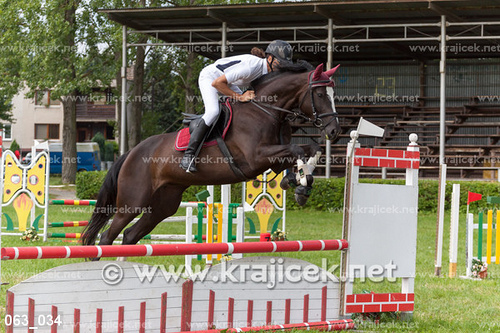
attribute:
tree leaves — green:
[5, 7, 91, 96]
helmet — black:
[266, 40, 295, 72]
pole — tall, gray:
[436, 11, 448, 171]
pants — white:
[190, 62, 245, 127]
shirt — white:
[214, 47, 267, 87]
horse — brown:
[55, 52, 349, 249]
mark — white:
[325, 84, 341, 126]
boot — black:
[179, 117, 209, 172]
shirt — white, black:
[209, 44, 270, 90]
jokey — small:
[178, 38, 295, 173]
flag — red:
[466, 188, 486, 203]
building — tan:
[2, 58, 74, 160]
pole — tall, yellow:
[481, 206, 495, 271]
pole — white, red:
[1, 239, 352, 266]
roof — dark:
[97, 1, 494, 79]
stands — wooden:
[279, 94, 499, 179]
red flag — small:
[466, 190, 481, 203]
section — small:
[452, 112, 485, 146]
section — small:
[456, 108, 483, 133]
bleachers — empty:
[330, 103, 493, 170]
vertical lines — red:
[11, 272, 353, 331]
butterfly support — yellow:
[231, 173, 300, 241]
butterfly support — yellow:
[4, 140, 58, 240]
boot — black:
[176, 124, 210, 178]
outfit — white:
[185, 48, 261, 126]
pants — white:
[178, 66, 240, 145]